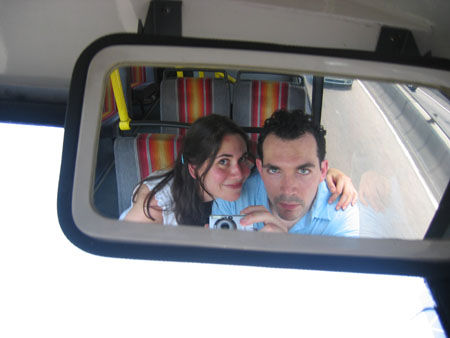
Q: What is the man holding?
A: Camera.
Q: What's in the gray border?
A: Two people taking a selfie.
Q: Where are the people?
A: On a bus.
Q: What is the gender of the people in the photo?
A: One is a man and one is a woman.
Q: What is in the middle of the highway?
A: A cement guard rail.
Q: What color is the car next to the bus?
A: Blue.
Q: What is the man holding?
A: A camera.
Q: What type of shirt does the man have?
A: A button down shirt.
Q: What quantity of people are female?
A: 1.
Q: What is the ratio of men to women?
A: 1:1.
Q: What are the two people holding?
A: Camera.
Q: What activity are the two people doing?
A: Taking a picture.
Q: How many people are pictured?
A: Two.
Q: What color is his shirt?
A: Light blue.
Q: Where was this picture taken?
A: On a bus.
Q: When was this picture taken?
A: Daytime.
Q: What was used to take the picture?
A: Digital camera.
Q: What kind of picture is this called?
A: Selfie.